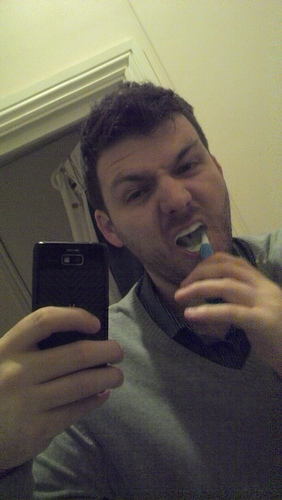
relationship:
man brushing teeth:
[26, 77, 280, 431] [177, 226, 206, 257]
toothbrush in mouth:
[190, 231, 219, 273] [166, 218, 219, 256]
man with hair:
[26, 77, 280, 431] [71, 73, 198, 144]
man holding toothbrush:
[26, 77, 280, 431] [190, 231, 219, 273]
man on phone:
[26, 77, 280, 431] [24, 229, 116, 366]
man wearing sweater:
[26, 77, 280, 431] [32, 234, 277, 499]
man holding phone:
[26, 77, 280, 431] [24, 229, 116, 366]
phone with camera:
[24, 229, 116, 366] [54, 251, 87, 268]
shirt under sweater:
[145, 284, 257, 358] [32, 234, 277, 499]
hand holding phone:
[6, 305, 128, 445] [24, 229, 116, 366]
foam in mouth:
[181, 231, 210, 244] [166, 218, 219, 256]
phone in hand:
[24, 229, 116, 366] [6, 305, 128, 445]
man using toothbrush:
[26, 77, 280, 431] [190, 231, 219, 273]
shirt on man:
[145, 284, 257, 358] [26, 77, 280, 431]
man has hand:
[26, 77, 280, 431] [6, 305, 128, 445]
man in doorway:
[26, 77, 280, 431] [0, 43, 197, 324]